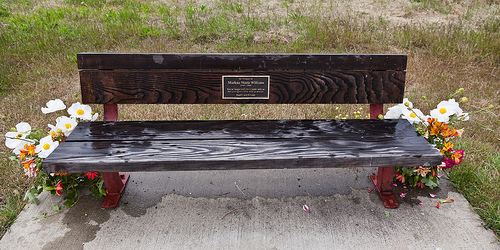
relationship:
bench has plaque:
[44, 47, 438, 220] [220, 72, 274, 101]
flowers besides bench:
[4, 95, 468, 191] [44, 47, 438, 220]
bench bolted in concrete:
[44, 47, 438, 220] [36, 181, 467, 243]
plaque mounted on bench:
[220, 72, 274, 101] [44, 47, 438, 220]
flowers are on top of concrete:
[4, 95, 468, 191] [36, 181, 467, 243]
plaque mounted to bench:
[220, 72, 274, 101] [44, 47, 438, 220]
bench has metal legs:
[44, 47, 438, 220] [90, 171, 402, 206]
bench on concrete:
[44, 47, 438, 220] [36, 181, 467, 243]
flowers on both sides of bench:
[4, 95, 468, 191] [44, 47, 438, 220]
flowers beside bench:
[4, 95, 468, 191] [44, 47, 438, 220]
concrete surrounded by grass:
[36, 181, 467, 243] [6, 3, 487, 53]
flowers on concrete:
[4, 95, 468, 191] [36, 181, 467, 243]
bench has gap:
[44, 47, 438, 220] [88, 103, 394, 118]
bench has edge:
[44, 47, 438, 220] [43, 157, 447, 167]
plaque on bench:
[220, 72, 274, 101] [44, 47, 438, 220]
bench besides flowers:
[44, 47, 438, 220] [4, 95, 468, 191]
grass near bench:
[6, 3, 487, 53] [44, 47, 438, 220]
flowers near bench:
[4, 95, 468, 191] [44, 47, 438, 220]